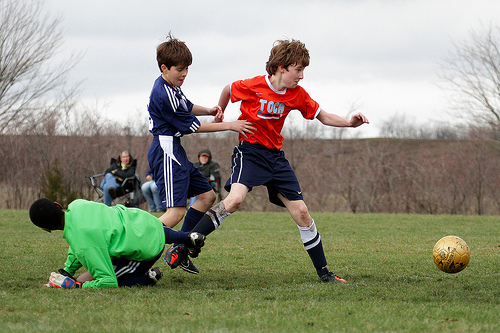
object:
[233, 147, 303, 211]
shorts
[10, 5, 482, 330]
scene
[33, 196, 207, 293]
boys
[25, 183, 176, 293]
shirt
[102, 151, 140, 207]
man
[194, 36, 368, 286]
boy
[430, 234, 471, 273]
ball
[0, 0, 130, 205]
trees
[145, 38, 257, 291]
boy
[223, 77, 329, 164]
jersey